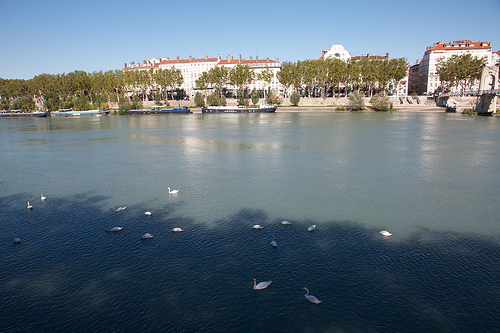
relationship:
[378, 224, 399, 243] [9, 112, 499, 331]
bird in water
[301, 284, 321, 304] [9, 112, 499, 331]
bird in water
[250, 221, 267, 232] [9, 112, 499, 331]
bird in water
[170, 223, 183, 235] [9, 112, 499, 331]
bird in water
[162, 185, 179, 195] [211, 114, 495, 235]
bird in water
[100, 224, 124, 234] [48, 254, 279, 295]
bird in water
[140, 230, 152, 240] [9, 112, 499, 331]
bird in water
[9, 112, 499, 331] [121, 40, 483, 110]
water in front of buildings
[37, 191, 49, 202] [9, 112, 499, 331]
bird in water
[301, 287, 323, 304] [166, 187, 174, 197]
bird has neck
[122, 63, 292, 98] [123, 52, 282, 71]
white building with red roof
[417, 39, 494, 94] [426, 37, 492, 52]
building with roof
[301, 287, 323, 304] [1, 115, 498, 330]
bird in canal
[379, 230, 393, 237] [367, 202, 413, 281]
bird in canel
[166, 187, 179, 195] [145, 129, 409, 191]
bird in canal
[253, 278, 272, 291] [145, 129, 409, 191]
bird in canal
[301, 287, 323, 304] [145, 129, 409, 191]
bird in canal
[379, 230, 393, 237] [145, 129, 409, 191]
bird in canal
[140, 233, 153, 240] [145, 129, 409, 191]
bird in canal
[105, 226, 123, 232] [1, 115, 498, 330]
bird in canal